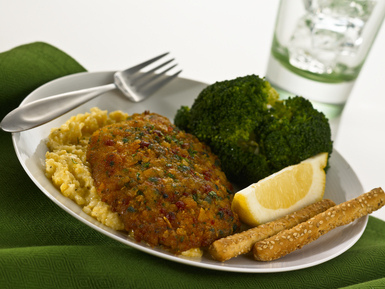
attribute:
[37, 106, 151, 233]
egg — cooked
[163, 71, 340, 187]
broccoli — steamed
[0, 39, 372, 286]
table cloth — green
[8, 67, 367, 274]
plate — white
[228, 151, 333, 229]
lemon — cut up, sliced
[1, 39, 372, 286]
table mat — green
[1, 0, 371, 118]
background — white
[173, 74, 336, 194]
something — green